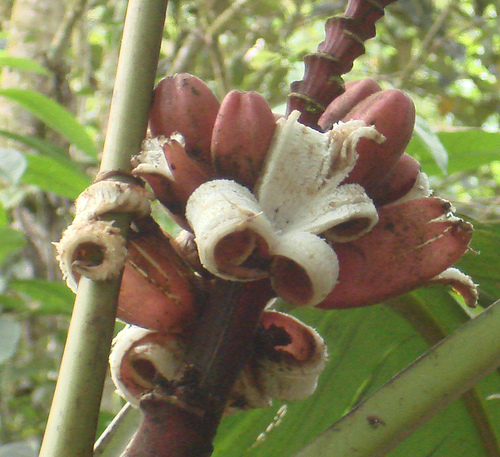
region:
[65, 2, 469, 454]
bad bananas on a tree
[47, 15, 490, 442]
bad bananas on a branch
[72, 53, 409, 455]
open bananas on a branch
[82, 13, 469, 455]
open bananas on a tree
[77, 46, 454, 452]
open red bananas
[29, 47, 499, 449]
red open bananas on a branch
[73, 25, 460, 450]
red open bananas on a tree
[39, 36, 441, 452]
bananas that are outside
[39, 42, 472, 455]
red bananas that are outside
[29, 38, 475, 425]
open bananas that are outside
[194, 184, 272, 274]
peel of the banana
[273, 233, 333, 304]
peel of the banana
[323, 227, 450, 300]
peel of the banana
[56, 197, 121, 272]
peel of the banana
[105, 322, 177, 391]
peel of the banana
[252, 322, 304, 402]
peel of the banana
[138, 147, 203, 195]
peel of the banana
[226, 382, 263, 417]
peel of the banana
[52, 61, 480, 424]
a hand of bananas on a banana tree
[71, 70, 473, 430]
the bananas grow on a red banana tree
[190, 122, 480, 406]
the bananas have ripened on the tree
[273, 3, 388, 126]
the banana stalk is red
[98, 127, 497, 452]
the banana leaves are green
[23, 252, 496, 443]
the banana leaf stalk is green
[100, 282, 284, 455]
the red stalk supports the red bananas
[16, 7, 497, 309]
trees are in the background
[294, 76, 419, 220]
the red bananas are short and fat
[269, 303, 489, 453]
the leaves of the bananas are used in cooking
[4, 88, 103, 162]
The leaf is green.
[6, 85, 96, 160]
The leaf is large.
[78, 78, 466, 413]
The peels are purple.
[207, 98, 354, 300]
The peel is open.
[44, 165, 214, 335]
THe peel is wrapped around the stick.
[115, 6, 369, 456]
The stem is purple.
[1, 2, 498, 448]
The sun is shining.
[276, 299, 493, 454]
The stem is green.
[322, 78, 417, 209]
This one is not open.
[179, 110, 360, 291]
It is white on the inside.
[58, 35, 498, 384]
a branch of bananas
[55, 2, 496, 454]
a banana on trees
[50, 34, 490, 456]
bananas on a tree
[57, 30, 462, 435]
red bananas on a branch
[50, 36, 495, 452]
red bananas on a tree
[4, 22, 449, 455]
a banana that is outside